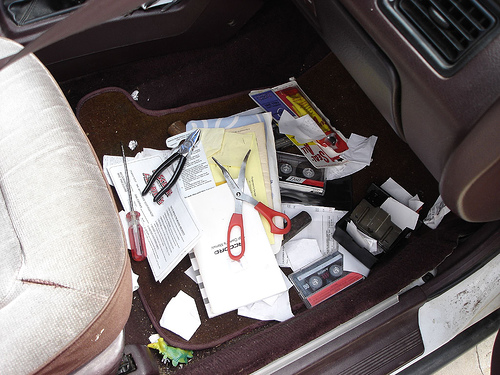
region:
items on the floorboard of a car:
[105, 92, 417, 295]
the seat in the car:
[4, 45, 134, 367]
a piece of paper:
[158, 288, 205, 343]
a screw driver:
[116, 140, 152, 264]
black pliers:
[143, 130, 203, 192]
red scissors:
[213, 145, 299, 259]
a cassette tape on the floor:
[286, 248, 367, 298]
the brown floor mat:
[90, 83, 345, 337]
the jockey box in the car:
[312, 6, 406, 130]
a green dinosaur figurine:
[148, 329, 192, 361]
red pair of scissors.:
[207, 147, 290, 259]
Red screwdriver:
[115, 141, 150, 260]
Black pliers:
[139, 126, 206, 203]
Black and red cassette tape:
[283, 249, 366, 309]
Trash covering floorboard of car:
[56, 61, 488, 363]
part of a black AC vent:
[368, 0, 498, 75]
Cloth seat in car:
[0, 30, 136, 371]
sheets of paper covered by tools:
[101, 100, 311, 321]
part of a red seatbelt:
[0, 0, 157, 77]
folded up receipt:
[156, 287, 206, 342]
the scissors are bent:
[210, 149, 252, 164]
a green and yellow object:
[145, 335, 192, 367]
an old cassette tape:
[288, 253, 361, 306]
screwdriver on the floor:
[117, 144, 147, 259]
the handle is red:
[125, 210, 147, 259]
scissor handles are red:
[225, 201, 292, 258]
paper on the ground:
[251, 78, 353, 168]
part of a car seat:
[1, 38, 131, 374]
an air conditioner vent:
[377, 0, 499, 73]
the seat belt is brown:
[0, 0, 145, 72]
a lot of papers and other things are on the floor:
[67, 79, 457, 364]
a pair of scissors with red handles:
[197, 147, 296, 262]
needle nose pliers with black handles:
[139, 128, 204, 202]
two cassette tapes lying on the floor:
[269, 136, 361, 308]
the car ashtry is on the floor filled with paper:
[330, 194, 425, 269]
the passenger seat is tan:
[0, 32, 137, 373]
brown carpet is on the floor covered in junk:
[55, 63, 460, 373]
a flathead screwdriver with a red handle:
[112, 137, 147, 267]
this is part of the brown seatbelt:
[1, 2, 152, 76]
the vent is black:
[377, 1, 499, 80]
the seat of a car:
[2, 38, 123, 366]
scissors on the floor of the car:
[208, 150, 282, 248]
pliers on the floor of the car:
[142, 122, 199, 199]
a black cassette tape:
[287, 247, 365, 294]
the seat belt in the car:
[1, 2, 123, 58]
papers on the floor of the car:
[258, 72, 358, 177]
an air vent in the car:
[388, 0, 496, 61]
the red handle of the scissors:
[225, 213, 297, 259]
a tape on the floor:
[274, 148, 334, 191]